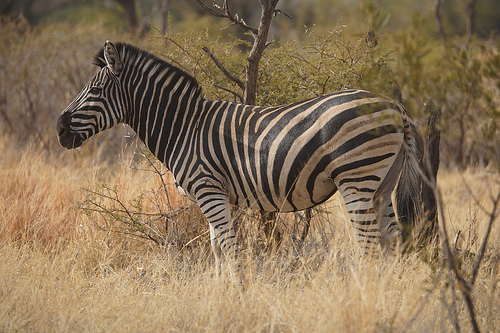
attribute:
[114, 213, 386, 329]
grass — tall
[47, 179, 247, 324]
grass — light brown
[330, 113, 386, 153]
lines — tannish-green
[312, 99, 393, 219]
stripes — black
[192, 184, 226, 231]
lines — black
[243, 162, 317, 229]
stipes — thinner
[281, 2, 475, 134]
tree — small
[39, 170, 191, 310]
grass — tall, brown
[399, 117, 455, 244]
zebra's tail — long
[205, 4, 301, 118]
tree — small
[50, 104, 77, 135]
nose — black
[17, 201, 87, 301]
grass — tall, brown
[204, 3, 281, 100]
tree — small, bare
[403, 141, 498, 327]
twigs — some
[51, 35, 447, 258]
zebra — one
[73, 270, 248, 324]
grass — brown, yellow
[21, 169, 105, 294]
grass — yellow, brown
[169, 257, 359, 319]
grass — brown, yellow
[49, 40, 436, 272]
zebra — black, white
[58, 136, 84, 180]
grass — blade, light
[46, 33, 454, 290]
zebra — one, standing, black, white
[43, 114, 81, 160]
nose — black